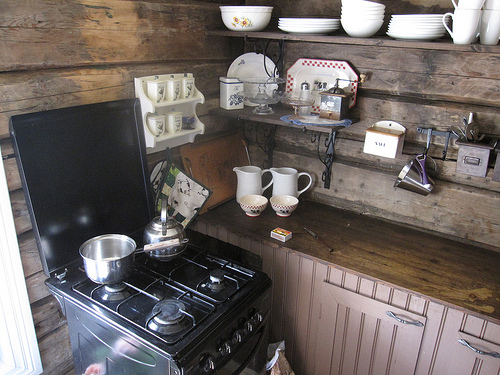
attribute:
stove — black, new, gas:
[52, 252, 284, 374]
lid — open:
[8, 94, 157, 273]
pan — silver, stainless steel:
[78, 232, 144, 283]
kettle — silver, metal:
[148, 205, 190, 261]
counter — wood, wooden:
[210, 202, 498, 316]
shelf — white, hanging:
[142, 122, 207, 140]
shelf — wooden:
[221, 98, 346, 133]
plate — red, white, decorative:
[286, 61, 358, 109]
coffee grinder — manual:
[316, 75, 359, 120]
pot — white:
[148, 115, 165, 138]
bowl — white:
[215, 9, 275, 29]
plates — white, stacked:
[388, 8, 450, 39]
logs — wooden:
[4, 7, 251, 102]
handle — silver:
[388, 309, 423, 328]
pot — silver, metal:
[79, 231, 137, 280]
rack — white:
[137, 74, 207, 142]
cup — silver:
[400, 158, 438, 198]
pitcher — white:
[229, 160, 271, 195]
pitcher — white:
[268, 160, 317, 196]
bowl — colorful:
[237, 194, 272, 218]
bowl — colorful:
[271, 195, 299, 215]